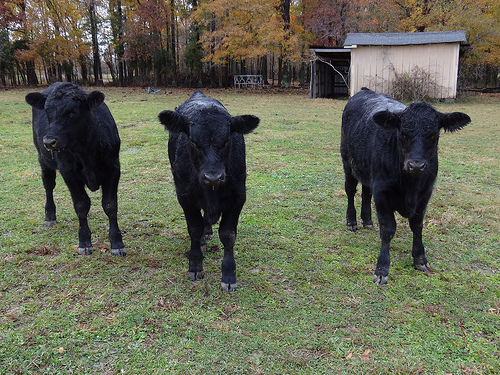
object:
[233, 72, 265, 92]
metal fence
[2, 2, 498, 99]
trees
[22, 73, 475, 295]
black cows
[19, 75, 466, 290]
cows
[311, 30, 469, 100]
shed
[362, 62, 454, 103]
dead foliage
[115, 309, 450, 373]
field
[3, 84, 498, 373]
property